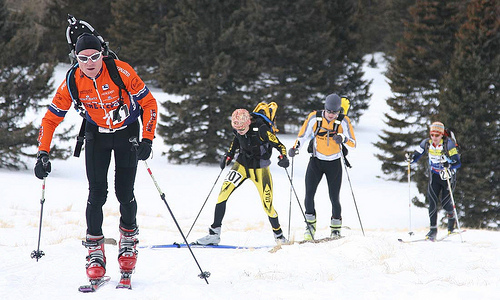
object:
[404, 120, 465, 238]
people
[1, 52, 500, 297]
snow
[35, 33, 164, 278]
man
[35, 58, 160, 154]
clothes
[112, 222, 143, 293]
skis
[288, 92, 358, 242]
person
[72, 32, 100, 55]
hat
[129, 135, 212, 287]
ski pole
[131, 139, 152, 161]
left hand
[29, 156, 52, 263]
ski pole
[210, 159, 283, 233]
pants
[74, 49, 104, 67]
goggles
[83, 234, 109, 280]
ski boot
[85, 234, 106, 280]
left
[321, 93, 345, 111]
hat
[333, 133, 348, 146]
left hand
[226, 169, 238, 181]
number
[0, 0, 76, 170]
tree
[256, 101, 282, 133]
snowshoes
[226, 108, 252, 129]
hat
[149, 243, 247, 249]
ski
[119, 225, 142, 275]
ski boots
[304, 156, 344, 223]
pants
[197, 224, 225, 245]
ski boot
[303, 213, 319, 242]
ski boot